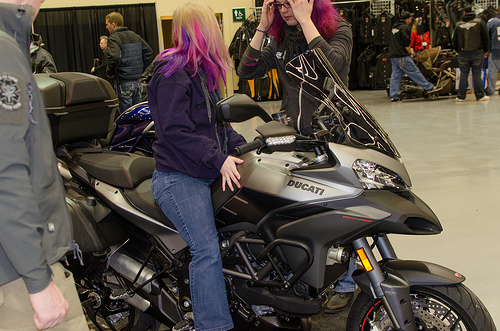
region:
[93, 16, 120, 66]
Man drinking coffee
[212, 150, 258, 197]
Woman's left hand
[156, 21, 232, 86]
Purple and pink hair is long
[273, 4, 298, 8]
Woman has glasses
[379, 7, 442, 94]
Man wearing black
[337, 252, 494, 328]
Front wheel of bike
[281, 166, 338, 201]
Ducati logo on motorcycle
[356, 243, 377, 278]
Yellow reflector above wheel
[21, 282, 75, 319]
Right hand of man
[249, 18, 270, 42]
Wristband on woman's arm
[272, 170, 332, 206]
small logo for ducati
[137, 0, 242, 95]
girl with purple and pink hair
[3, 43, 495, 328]
black and silver motorcycle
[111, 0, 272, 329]
girl sitting on motorcycle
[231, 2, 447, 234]
girl in glasses looking at bike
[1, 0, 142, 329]
man looking at motorcycle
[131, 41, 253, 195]
long sleeve purple jacket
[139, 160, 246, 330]
light blue women's jeans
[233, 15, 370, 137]
long sleeve grey shirt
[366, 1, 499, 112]
people at motorcycle convention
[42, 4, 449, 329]
A girl sitting on a motorcycle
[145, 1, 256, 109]
A girl with pink in her hair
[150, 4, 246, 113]
A girl with purple in her hair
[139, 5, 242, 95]
A girl with pink and purple in her hair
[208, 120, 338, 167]
A handle bar on a motorcycle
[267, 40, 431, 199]
A windshield on a motorcycle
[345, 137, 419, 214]
A headlight on a motorcycle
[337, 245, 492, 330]
The front tire on a motorcycle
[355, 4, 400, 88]
Shirts hanging on a rack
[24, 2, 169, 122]
Black curtains hanging in the distance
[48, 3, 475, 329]
lady sitting on motorcycle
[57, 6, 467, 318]
lady sitting on Ducati motorcycle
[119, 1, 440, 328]
two friends checking out a motorcycle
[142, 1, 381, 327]
two friends with pink hair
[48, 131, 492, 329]
Ducati motorcycle at a show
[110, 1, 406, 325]
two ladies talking about a motorcycle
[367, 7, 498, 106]
men looking at riding gear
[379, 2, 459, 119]
man pushing stroller at trade show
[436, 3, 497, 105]
man standing in Harley jacket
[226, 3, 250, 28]
blue restroom sign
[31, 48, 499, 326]
the motorcycle is black and silver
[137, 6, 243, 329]
a girl is sitting on the bike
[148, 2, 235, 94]
the hair is streaked on the girl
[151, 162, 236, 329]
the girl is wearing blue jeans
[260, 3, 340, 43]
the girl has red hair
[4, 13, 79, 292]
the man has a gray parka on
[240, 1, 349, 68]
the girl has both hands on her head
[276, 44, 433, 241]
the bike has a windshield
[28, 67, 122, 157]
a helmet box is on the back of the cycle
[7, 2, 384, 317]
the man is looking at the bike